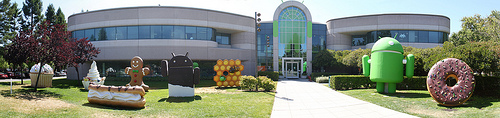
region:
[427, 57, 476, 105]
large pink donut with sprinkles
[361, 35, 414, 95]
green Android robot statue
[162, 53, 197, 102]
large Android ice cream sandwich statue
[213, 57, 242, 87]
large statue of honeycomb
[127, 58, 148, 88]
large gingerbread man statue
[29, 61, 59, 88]
big cupcake statue behind a tree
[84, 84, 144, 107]
big eclair statue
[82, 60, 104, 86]
large dish of ice cream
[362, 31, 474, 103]
green robot statue next to a giant donut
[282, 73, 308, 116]
sidewalk leading up to the door of the building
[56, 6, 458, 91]
a multi story white building.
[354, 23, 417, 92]
a android robot in front of a building.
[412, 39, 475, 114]
a large doughnut in front of a building.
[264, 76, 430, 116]
A sidewalk in front of a building.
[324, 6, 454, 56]
a section of a building.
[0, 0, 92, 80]
a tall leafy tree.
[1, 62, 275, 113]
a field of green grass.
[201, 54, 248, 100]
a sculpture on a lawn.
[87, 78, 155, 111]
a wall on a green field.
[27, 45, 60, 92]
a boulder in front of a building.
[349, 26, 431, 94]
a giant green robot.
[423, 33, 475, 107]
a giant pink doughnut.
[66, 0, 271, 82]
a multi story building.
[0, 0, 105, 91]
a forest of trees.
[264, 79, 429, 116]
a paved sidewalk near a robot.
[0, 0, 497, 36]
a section of clear blue sky.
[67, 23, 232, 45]
a row of glass windows.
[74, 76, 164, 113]
a sculpture on a lawn.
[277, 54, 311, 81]
an entrance to a building.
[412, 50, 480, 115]
large fake pink doughnut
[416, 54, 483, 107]
large fake sprinkled doughnut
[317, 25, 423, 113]
large green robot on grass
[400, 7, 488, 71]
tall green trees and bushes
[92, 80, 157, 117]
large fake chocolate cream puff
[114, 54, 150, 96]
large fake ginger bread man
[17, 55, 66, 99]
large fake cupcake with white frosting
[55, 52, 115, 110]
large bowl of soft seve ice cream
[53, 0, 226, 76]
building with small windows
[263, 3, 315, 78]
building with lots of small windows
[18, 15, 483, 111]
picture taken outdoors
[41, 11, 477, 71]
picture taken during the day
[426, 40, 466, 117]
a doughnut on the ground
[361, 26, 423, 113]
a large android statute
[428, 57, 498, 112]
the dougnut is pink and with sprinkles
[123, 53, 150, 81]
a gingerbread man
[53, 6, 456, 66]
a building is in the background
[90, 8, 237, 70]
the building is round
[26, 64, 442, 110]
large dessert items on the ground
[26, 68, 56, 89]
a very large cupcake